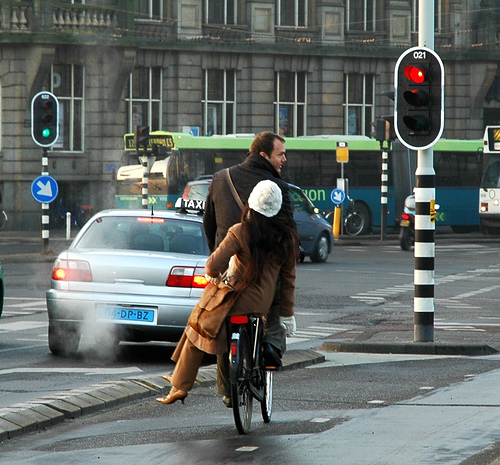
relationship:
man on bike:
[205, 144, 285, 277] [225, 298, 292, 424]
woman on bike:
[189, 175, 276, 314] [225, 298, 292, 424]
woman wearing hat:
[189, 175, 276, 314] [243, 179, 284, 224]